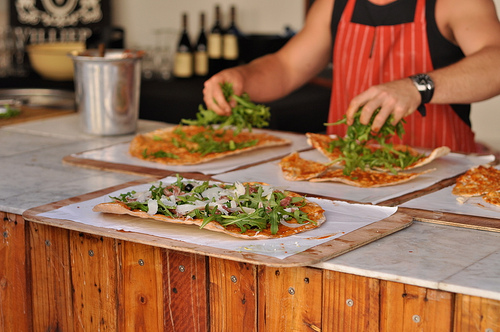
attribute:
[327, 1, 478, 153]
apron — red, white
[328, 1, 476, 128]
tank — black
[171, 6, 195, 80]
bottle — wine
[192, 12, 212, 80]
bottle — wine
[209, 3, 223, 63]
bottle — wine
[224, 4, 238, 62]
bottle — wine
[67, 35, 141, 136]
container — full of sauce, tall, metallic, stainless steel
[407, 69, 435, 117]
watch — silver, black, grey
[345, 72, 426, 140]
hand — white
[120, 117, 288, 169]
pizza — thin, homemade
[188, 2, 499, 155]
chef — woman, man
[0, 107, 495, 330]
counter — rustic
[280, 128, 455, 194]
tortilla — broken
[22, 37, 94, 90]
bowl — yellow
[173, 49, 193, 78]
label — yellow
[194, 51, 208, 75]
label — yellow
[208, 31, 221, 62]
label — yellow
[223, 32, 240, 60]
label — yellow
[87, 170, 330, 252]
tortilla — thin